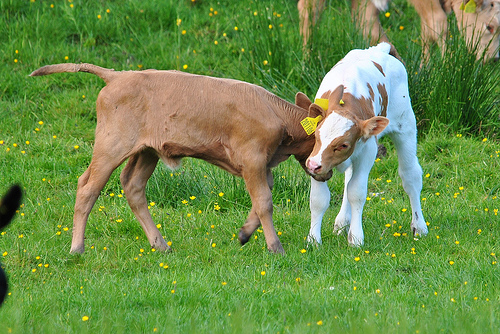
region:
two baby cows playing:
[29, 35, 448, 254]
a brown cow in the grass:
[52, 45, 300, 249]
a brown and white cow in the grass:
[319, 34, 434, 229]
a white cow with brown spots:
[352, 64, 399, 113]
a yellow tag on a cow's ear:
[300, 98, 322, 137]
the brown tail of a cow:
[30, 43, 110, 93]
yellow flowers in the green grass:
[132, 257, 328, 313]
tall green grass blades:
[437, 30, 494, 132]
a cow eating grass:
[425, 7, 499, 69]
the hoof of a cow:
[235, 220, 256, 246]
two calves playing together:
[20, 20, 455, 263]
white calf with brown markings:
[297, 35, 435, 250]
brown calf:
[27, 54, 324, 263]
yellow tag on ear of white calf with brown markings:
[298, 107, 324, 137]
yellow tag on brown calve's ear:
[315, 93, 335, 108]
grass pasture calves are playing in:
[8, 65, 490, 332]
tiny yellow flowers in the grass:
[12, 5, 499, 331]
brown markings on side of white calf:
[355, 58, 402, 120]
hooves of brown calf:
[68, 235, 285, 255]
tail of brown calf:
[25, 56, 105, 82]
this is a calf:
[306, 45, 438, 275]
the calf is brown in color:
[185, 90, 230, 142]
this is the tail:
[29, 55, 99, 88]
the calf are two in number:
[86, 42, 432, 276]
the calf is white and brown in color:
[356, 80, 380, 122]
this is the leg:
[398, 125, 434, 243]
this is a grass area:
[279, 248, 378, 332]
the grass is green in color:
[345, 268, 452, 331]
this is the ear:
[358, 113, 391, 147]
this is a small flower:
[259, 57, 280, 67]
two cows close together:
[57, 25, 437, 250]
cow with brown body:
[55, 50, 335, 262]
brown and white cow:
[312, 37, 412, 242]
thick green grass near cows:
[425, 165, 496, 305]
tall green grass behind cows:
[325, 21, 485, 131]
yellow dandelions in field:
[146, 196, 286, 322]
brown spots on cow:
[325, 56, 395, 141]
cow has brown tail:
[34, 28, 132, 125]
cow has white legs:
[298, 128, 425, 268]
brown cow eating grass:
[294, 1, 492, 63]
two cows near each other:
[82, 45, 483, 287]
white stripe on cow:
[301, 108, 352, 182]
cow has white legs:
[291, 145, 376, 255]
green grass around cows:
[354, 220, 472, 320]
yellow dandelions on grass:
[285, 228, 432, 332]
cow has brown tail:
[30, 61, 122, 91]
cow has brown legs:
[45, 118, 289, 252]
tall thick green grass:
[292, 23, 492, 135]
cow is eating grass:
[281, 0, 491, 102]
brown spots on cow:
[335, 61, 433, 152]